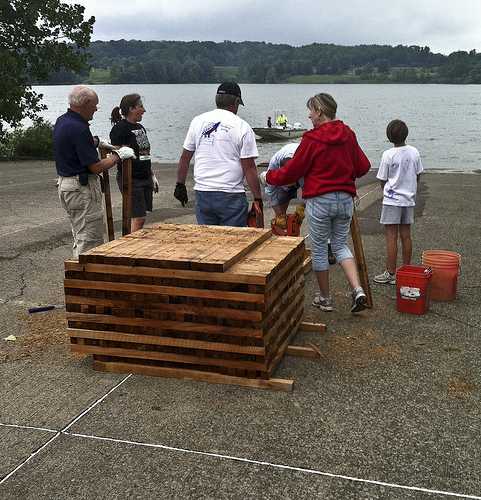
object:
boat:
[251, 122, 307, 140]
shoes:
[311, 294, 335, 313]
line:
[0, 422, 479, 499]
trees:
[265, 67, 278, 85]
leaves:
[86, 52, 92, 55]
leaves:
[88, 16, 95, 25]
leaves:
[38, 94, 43, 100]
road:
[3, 161, 480, 496]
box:
[394, 264, 433, 316]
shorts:
[379, 204, 414, 225]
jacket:
[266, 120, 372, 202]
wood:
[63, 222, 326, 392]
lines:
[0, 370, 136, 487]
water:
[356, 76, 455, 138]